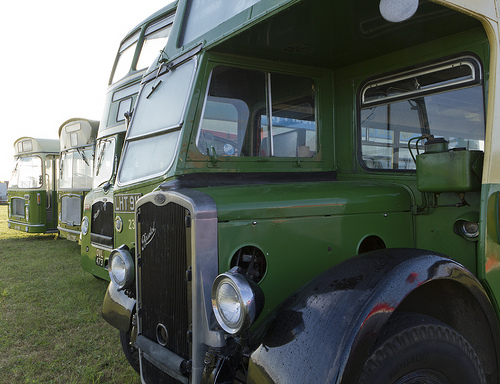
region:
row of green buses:
[26, 80, 451, 380]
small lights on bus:
[197, 282, 264, 335]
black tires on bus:
[358, 326, 498, 376]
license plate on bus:
[104, 181, 161, 227]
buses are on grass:
[10, 126, 440, 366]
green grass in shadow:
[18, 236, 104, 378]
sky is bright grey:
[27, 18, 111, 116]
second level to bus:
[106, 41, 178, 123]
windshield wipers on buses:
[60, 130, 86, 190]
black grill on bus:
[129, 188, 244, 378]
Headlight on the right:
[203, 265, 266, 345]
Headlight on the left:
[98, 241, 141, 293]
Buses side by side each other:
[1, 40, 476, 382]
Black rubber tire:
[358, 297, 489, 382]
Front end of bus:
[117, 189, 264, 382]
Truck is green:
[96, 0, 498, 366]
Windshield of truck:
[347, 60, 492, 180]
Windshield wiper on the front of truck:
[133, 47, 187, 112]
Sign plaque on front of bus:
[108, 190, 143, 214]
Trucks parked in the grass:
[6, 22, 391, 382]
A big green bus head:
[164, 39, 496, 341]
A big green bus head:
[87, 66, 107, 275]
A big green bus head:
[47, 121, 83, 242]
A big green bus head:
[4, 136, 52, 238]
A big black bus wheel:
[372, 288, 499, 379]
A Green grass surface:
[42, 340, 123, 380]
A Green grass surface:
[10, 242, 83, 304]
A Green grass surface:
[1, 315, 52, 376]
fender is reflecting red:
[341, 251, 421, 362]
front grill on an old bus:
[121, 192, 199, 382]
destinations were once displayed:
[0, 102, 115, 159]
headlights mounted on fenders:
[105, 237, 273, 341]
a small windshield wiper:
[136, 54, 179, 104]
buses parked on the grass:
[0, 0, 186, 382]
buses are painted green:
[3, 10, 401, 381]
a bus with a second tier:
[73, 0, 178, 289]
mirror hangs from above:
[346, 2, 448, 39]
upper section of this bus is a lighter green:
[381, 0, 496, 192]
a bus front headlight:
[209, 273, 261, 338]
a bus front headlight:
[108, 243, 134, 293]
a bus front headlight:
[81, 218, 86, 233]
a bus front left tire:
[357, 316, 488, 381]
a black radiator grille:
[136, 200, 189, 360]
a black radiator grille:
[88, 201, 113, 245]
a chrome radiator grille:
[59, 194, 79, 224]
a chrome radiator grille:
[9, 198, 25, 215]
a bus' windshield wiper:
[141, 58, 164, 98]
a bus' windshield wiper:
[91, 140, 106, 175]